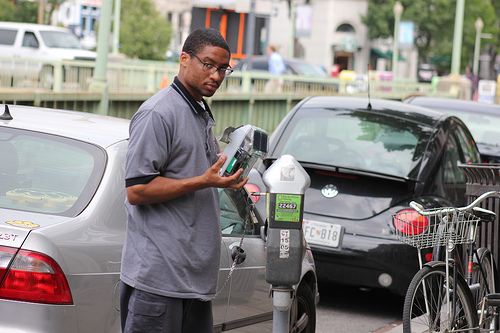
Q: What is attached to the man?
A: Key.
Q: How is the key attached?
A: Chain.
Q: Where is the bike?
A: On the right.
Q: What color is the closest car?
A: Silver.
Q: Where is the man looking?
A: At the camera.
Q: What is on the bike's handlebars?
A: Basket.